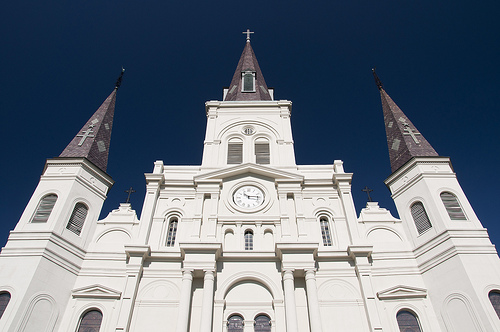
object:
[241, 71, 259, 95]
window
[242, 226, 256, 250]
window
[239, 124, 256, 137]
vent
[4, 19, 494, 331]
building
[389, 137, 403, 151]
diamond shape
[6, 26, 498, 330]
church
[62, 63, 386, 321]
church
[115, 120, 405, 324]
building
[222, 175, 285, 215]
clock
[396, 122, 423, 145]
cross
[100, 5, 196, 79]
sky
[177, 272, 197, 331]
pillar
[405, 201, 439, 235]
window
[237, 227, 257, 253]
window case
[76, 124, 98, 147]
cross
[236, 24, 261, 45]
cross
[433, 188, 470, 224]
window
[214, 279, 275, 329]
arch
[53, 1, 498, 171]
sky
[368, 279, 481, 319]
accent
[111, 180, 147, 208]
cross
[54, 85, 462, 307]
church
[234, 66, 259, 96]
window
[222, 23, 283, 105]
spire